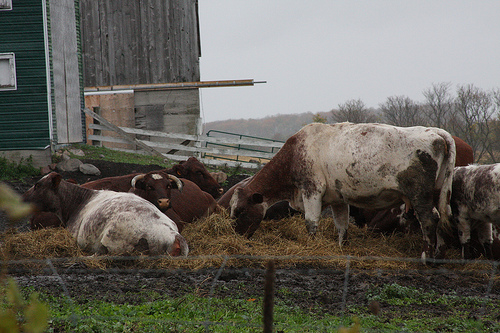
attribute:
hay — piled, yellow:
[1, 203, 499, 280]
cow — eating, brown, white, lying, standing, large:
[227, 121, 456, 265]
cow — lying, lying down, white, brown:
[20, 169, 190, 258]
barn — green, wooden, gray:
[0, 1, 201, 173]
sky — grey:
[197, 0, 499, 122]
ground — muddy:
[1, 145, 500, 332]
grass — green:
[0, 141, 500, 332]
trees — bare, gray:
[307, 83, 500, 164]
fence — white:
[84, 106, 287, 170]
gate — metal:
[203, 130, 286, 167]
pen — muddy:
[0, 107, 499, 332]